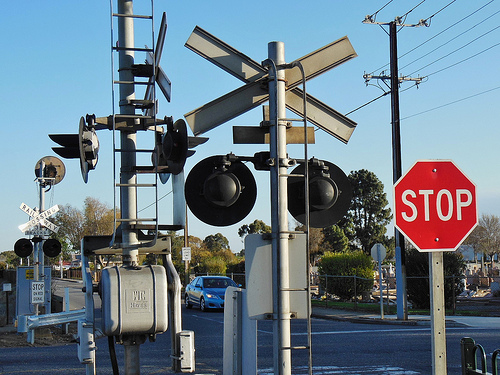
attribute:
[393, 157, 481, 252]
sign — red, white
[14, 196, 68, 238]
crossing sign — white, black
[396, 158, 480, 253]
stop sign — red, white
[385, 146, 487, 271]
sign — red, white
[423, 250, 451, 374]
pole — grey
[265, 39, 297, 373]
pole — grey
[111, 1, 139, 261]
pole — grey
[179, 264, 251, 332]
car — silver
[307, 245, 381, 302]
bush — trimmed, funny shape